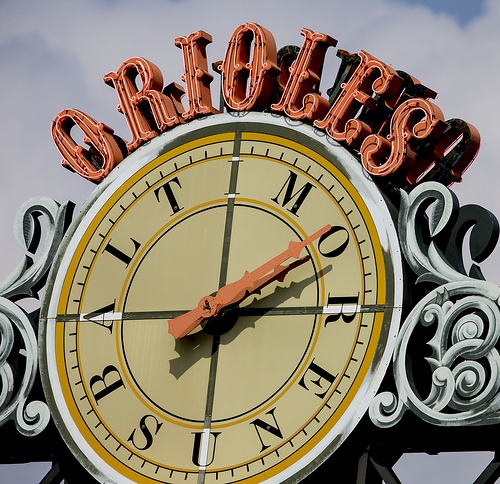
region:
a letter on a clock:
[294, 353, 353, 410]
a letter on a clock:
[245, 405, 285, 451]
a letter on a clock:
[188, 423, 213, 468]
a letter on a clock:
[123, 413, 171, 457]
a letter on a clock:
[90, 360, 136, 410]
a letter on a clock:
[73, 299, 137, 346]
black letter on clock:
[268, 168, 315, 218]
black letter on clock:
[316, 222, 349, 259]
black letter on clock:
[323, 290, 360, 330]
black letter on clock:
[296, 357, 336, 402]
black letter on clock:
[250, 405, 286, 451]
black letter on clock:
[124, 410, 163, 457]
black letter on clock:
[89, 363, 126, 410]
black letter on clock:
[81, 299, 114, 332]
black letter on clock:
[100, 234, 140, 271]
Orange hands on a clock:
[163, 223, 330, 340]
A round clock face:
[27, 108, 409, 483]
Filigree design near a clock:
[373, 185, 498, 432]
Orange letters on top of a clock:
[49, 20, 481, 186]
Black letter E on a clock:
[296, 362, 338, 399]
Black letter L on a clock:
[96, 236, 141, 266]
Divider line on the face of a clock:
[197, 327, 214, 482]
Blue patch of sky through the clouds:
[430, 1, 485, 23]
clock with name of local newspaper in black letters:
[9, 109, 489, 479]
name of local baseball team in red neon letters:
[48, 21, 445, 201]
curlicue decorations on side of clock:
[356, 183, 497, 457]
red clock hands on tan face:
[59, 132, 386, 481]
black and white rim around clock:
[38, 112, 404, 480]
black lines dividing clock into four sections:
[37, 112, 407, 477]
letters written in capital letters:
[49, 19, 441, 476]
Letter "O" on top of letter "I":
[215, 20, 272, 200]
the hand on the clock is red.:
[187, 256, 322, 339]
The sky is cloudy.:
[25, 18, 158, 70]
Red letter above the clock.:
[107, 44, 407, 141]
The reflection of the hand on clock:
[245, 269, 327, 327]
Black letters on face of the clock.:
[108, 374, 323, 460]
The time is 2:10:
[208, 208, 327, 315]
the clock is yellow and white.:
[88, 177, 389, 444]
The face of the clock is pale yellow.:
[110, 220, 301, 378]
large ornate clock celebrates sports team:
[0, 23, 499, 482]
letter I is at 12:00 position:
[225, 157, 243, 197]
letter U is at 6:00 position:
[191, 429, 220, 467]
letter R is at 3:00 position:
[320, 291, 358, 324]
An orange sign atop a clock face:
[44, 19, 481, 177]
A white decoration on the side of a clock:
[368, 180, 499, 433]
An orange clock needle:
[165, 223, 335, 340]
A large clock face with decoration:
[42, 110, 398, 480]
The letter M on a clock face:
[268, 166, 316, 217]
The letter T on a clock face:
[144, 174, 192, 216]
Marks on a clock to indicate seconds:
[141, 181, 156, 188]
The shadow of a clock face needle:
[166, 259, 341, 379]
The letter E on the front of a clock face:
[298, 356, 341, 400]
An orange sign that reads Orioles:
[50, 21, 453, 186]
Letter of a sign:
[46, 105, 120, 187]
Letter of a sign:
[101, 53, 183, 149]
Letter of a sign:
[166, 25, 215, 122]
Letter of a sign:
[353, 89, 448, 183]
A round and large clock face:
[21, 113, 418, 483]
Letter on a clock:
[271, 165, 316, 223]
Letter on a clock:
[150, 178, 186, 220]